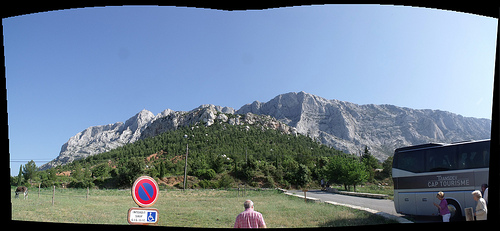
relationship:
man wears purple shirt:
[231, 199, 268, 230] [235, 206, 275, 227]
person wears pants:
[428, 190, 453, 222] [442, 210, 452, 222]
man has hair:
[231, 199, 268, 230] [239, 196, 257, 211]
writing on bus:
[421, 171, 476, 194] [378, 134, 498, 229]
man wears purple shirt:
[221, 192, 268, 229] [231, 209, 266, 231]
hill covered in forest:
[11, 122, 392, 189] [10, 110, 391, 194]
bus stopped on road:
[391, 137, 491, 225] [293, 185, 395, 228]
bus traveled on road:
[390, 137, 491, 225] [278, 178, 415, 220]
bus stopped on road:
[390, 137, 491, 225] [282, 186, 405, 216]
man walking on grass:
[231, 199, 268, 230] [203, 212, 232, 227]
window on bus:
[388, 143, 421, 176] [377, 128, 485, 217]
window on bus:
[416, 135, 457, 177] [377, 128, 485, 217]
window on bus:
[463, 143, 498, 170] [377, 128, 485, 217]